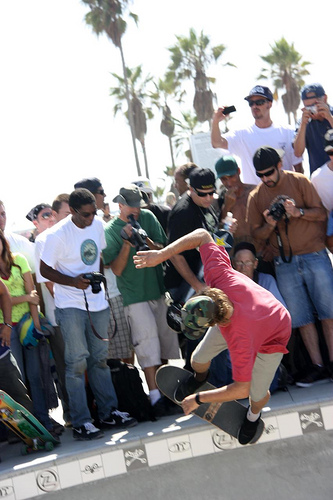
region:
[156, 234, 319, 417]
The man is skateboarding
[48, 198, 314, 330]
The men are holding cameras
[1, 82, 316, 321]
THere is only 1 woman shown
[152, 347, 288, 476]
The top of the board is black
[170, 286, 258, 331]
He is wearing a helmet for safety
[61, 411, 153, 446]
His shoes are Nike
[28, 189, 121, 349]
His tshirt is white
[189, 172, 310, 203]
They are wearing sunglasses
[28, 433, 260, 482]
The tiles are white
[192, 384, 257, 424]
He is wearing a watch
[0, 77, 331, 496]
Spectators watching skateboarder doing tricks with his skateboard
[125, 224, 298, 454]
Skateboarder doing tricks with his skateboard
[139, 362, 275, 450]
Black skateboard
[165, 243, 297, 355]
Skateboarder's red t shirt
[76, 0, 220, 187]
Tropical palm trees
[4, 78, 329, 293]
Crowd watching and taking pictures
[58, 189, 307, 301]
Different cameras crowd is using to record the skateboarder doing tricks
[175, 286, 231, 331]
Skateboarder's green camouflage hat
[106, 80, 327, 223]
Different hats people in the crowd are wearing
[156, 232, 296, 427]
Skateboarder's red shirt and khaki shorts outfit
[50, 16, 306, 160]
tall and slender palm trees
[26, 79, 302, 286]
many spectators with cameras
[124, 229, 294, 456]
skateboarder preforming jump trick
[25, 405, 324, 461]
row of tiles along rim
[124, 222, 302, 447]
skateboarder with lifted arm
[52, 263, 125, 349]
camera with strap hanging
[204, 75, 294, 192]
man lifting camera for shot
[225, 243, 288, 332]
man crouched behind skateboarder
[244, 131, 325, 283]
man holding camera to chest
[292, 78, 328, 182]
man holding camera to face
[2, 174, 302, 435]
crowd watching skateboarder do stunts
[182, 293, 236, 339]
a camouflage hat covers a head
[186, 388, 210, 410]
a black band around a wrist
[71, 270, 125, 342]
a hand holding a black camera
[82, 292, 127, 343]
a strap dangling from a camera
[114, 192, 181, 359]
a man filming an event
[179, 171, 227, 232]
a guy wearing black sunglasses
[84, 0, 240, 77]
palm trees tower over a crowd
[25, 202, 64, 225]
man wearing a black scarf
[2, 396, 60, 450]
a green and yellow skateboard leaning on a leg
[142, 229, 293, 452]
a man on a skateboard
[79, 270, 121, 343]
black extended lens camera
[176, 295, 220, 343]
an army pattern hat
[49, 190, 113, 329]
a man with a camera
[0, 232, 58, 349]
a girl holding a helmet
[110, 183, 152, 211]
hat with folded up sides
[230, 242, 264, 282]
an elderly man with glasses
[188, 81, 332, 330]
a group of men all wearing hats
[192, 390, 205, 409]
a black watch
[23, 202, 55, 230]
person wearing a bandana